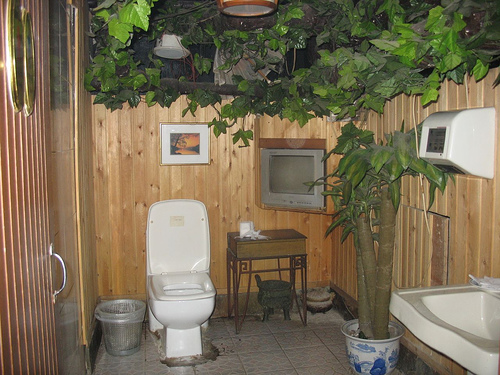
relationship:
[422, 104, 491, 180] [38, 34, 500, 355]
air hand dryer in bathroom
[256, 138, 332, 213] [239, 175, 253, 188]
tv in wall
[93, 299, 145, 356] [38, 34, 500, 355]
bucket in bathroom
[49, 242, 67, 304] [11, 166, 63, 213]
door handle on door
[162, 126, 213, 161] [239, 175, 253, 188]
picture on wall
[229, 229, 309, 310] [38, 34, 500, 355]
small table in bathroom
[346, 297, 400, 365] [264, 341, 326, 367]
potted plant on floor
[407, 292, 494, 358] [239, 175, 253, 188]
sink on wall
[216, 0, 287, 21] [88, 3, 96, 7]
light in ceiling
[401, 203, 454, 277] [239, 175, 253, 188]
access door in wall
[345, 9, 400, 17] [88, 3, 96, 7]
green ivy on ceiling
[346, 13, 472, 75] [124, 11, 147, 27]
tree has green leaves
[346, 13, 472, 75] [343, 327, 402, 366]
tree in flower pot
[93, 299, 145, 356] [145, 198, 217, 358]
bucket by toilet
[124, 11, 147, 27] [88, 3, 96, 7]
green leaves on ceiling